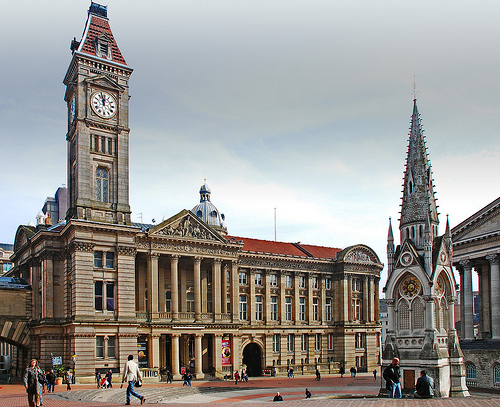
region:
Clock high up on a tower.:
[89, 89, 119, 121]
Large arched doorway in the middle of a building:
[237, 338, 267, 375]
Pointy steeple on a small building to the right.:
[396, 74, 441, 229]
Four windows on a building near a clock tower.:
[91, 248, 118, 317]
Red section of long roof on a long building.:
[224, 231, 341, 261]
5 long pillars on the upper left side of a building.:
[142, 249, 240, 322]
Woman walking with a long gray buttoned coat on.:
[22, 359, 42, 406]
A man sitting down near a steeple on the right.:
[415, 370, 435, 397]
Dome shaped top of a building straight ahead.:
[187, 177, 227, 232]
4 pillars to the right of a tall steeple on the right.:
[455, 256, 497, 339]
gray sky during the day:
[166, 43, 358, 175]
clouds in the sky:
[293, 113, 353, 235]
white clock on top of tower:
[76, 87, 158, 139]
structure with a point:
[338, 64, 469, 382]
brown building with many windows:
[26, 212, 345, 374]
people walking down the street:
[40, 363, 189, 403]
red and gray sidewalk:
[248, 379, 325, 405]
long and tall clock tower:
[45, 8, 180, 217]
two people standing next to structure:
[372, 352, 439, 401]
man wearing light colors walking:
[115, 352, 147, 401]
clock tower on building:
[56, 0, 148, 229]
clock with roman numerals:
[81, 87, 127, 129]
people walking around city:
[27, 341, 258, 402]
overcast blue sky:
[221, 27, 384, 162]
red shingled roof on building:
[227, 227, 347, 258]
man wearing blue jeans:
[114, 336, 162, 405]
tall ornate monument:
[362, 72, 477, 394]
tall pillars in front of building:
[145, 234, 247, 383]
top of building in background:
[188, 179, 237, 230]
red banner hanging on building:
[218, 336, 240, 378]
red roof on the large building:
[217, 218, 362, 263]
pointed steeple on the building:
[382, 65, 445, 137]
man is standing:
[369, 347, 411, 400]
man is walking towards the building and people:
[108, 354, 158, 404]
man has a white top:
[108, 343, 158, 404]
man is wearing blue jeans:
[98, 341, 165, 403]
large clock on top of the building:
[85, 89, 123, 118]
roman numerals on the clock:
[84, 83, 123, 125]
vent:
[95, 36, 119, 72]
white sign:
[40, 348, 77, 366]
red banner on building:
[219, 339, 234, 369]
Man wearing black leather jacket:
[413, 370, 436, 399]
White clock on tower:
[88, 86, 118, 121]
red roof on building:
[221, 232, 347, 260]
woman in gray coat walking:
[22, 353, 49, 405]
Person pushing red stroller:
[97, 367, 114, 387]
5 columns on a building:
[143, 252, 238, 324]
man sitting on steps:
[408, 370, 434, 398]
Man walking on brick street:
[117, 353, 147, 403]